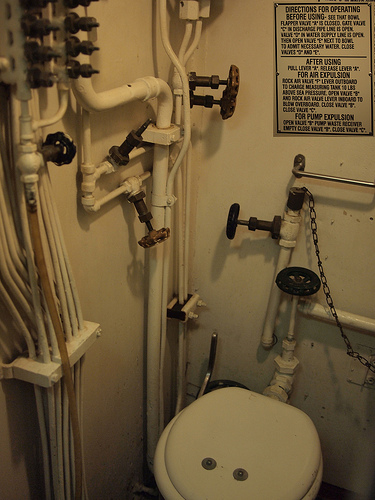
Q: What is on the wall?
A: Pipes.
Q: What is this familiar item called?
A: Toilet bowl base.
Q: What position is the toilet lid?
A: The lid is closed.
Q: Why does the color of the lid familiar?
A: It is standard white.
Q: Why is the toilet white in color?
A: First color manufactured.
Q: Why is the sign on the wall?
A: Usage directions.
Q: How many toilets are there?
A: One.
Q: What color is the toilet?
A: White.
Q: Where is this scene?
A: A bathroom.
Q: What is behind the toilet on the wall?
A: A sign.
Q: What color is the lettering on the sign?
A: Black.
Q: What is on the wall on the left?
A: Pipes.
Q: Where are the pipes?
A: On the wall on the left.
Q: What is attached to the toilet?
A: A chain.